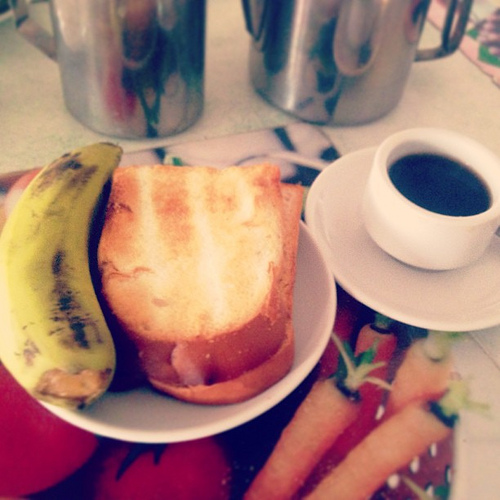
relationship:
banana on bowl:
[1, 139, 122, 414] [35, 214, 338, 448]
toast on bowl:
[94, 162, 289, 386] [35, 214, 338, 448]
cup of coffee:
[362, 125, 499, 273] [388, 149, 495, 217]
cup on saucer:
[362, 125, 499, 273] [300, 145, 499, 335]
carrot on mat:
[299, 375, 491, 499] [1, 120, 500, 499]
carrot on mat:
[378, 330, 469, 422] [1, 120, 500, 499]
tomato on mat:
[93, 434, 234, 499] [1, 120, 500, 499]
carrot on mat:
[325, 312, 399, 470] [1, 120, 500, 499]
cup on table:
[362, 125, 499, 273] [3, 0, 500, 377]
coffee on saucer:
[388, 149, 495, 217] [300, 145, 499, 335]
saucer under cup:
[300, 145, 499, 335] [362, 125, 499, 273]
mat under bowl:
[1, 120, 500, 499] [35, 214, 338, 448]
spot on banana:
[47, 248, 101, 351] [1, 139, 122, 414]